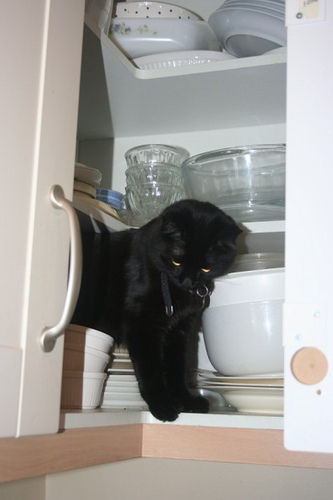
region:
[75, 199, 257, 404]
Black cat inside the cabinet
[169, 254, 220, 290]
The cat has yellow eyes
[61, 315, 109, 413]
Three dishes stacked on each other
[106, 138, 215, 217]
Three glasses stacked on second shelf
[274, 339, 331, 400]
Knob on front of cabinet door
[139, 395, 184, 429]
Cat has a small front paw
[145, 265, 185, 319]
Cat wearing a black collar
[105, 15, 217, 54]
Small pyrex dish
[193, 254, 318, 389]
Large plastic mixing bowl in cabinet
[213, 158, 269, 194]
Reflection of light on the glass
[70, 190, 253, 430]
a black cat in a cabinet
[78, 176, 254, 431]
black cat is looking down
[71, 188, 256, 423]
cat is over white dishes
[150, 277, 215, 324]
the black cat has a collar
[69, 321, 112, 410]
three bowls under a cat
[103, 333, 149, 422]
a pile of white dishes under a cat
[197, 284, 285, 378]
a bowl in front a cat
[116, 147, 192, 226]
bowl of glass in a shelf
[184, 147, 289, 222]
a big bowl over a cat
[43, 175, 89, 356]
silver handle of a cabinet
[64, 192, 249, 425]
black cat in the cabinet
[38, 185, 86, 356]
silver cabinet handle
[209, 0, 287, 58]
stack of white plates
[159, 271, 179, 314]
black strap hanging down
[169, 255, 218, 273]
small yellow slits for eyes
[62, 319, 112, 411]
stack of small white bowls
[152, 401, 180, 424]
paw hanging over the edge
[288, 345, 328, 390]
small light brown circle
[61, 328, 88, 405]
dark shadow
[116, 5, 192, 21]
blue dots on a white background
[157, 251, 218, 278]
yellow eyes of a cat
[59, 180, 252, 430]
small solid black cat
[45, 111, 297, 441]
black cat in cabinet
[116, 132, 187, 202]
small clear glass bowls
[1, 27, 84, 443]
small white cabinet door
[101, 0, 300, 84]
different dishes on shelf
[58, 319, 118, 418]
small white kitchen bowls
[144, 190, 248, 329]
small black cat with collar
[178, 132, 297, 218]
large glass mixing bowl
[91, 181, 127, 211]
small glass kitchen bowls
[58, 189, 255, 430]
a black cat inside a white cabinet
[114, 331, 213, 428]
front legs of cat in front of dishes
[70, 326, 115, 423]
bowls under a black cat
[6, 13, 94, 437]
door of cabinet is white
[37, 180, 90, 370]
handle of door is color silver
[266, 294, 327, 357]
white hinge of cabinet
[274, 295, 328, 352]
hinge of cabinet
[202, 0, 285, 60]
plate on top of cabinet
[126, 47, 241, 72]
a baking pan color white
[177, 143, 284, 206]
a bowl of glass